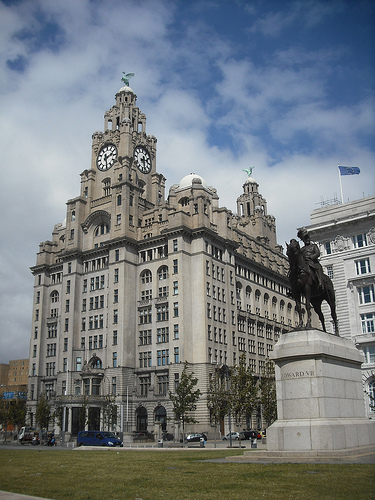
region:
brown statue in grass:
[277, 228, 370, 324]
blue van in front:
[76, 421, 129, 464]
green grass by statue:
[78, 456, 151, 489]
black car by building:
[182, 429, 220, 447]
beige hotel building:
[30, 259, 267, 371]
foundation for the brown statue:
[258, 319, 359, 454]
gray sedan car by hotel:
[212, 425, 250, 443]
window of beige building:
[68, 290, 129, 312]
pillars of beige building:
[57, 402, 99, 435]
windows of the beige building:
[196, 264, 237, 355]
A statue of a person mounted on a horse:
[260, 217, 371, 431]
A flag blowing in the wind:
[325, 148, 363, 203]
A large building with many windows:
[2, 65, 299, 452]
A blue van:
[67, 423, 134, 448]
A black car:
[170, 428, 209, 445]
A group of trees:
[165, 360, 285, 443]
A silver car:
[218, 427, 244, 442]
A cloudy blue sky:
[0, 0, 373, 147]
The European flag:
[325, 159, 365, 205]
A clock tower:
[70, 63, 175, 209]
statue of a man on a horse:
[265, 214, 350, 368]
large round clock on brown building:
[82, 109, 142, 194]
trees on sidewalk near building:
[168, 356, 266, 422]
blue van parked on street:
[56, 416, 126, 459]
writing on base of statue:
[268, 361, 324, 394]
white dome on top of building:
[161, 161, 224, 206]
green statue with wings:
[231, 155, 266, 196]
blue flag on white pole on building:
[324, 146, 369, 212]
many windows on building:
[25, 264, 274, 394]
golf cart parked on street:
[1, 414, 48, 456]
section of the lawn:
[97, 467, 114, 482]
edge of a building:
[203, 377, 204, 393]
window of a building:
[154, 384, 160, 386]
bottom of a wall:
[271, 451, 284, 455]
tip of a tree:
[245, 390, 250, 396]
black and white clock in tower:
[98, 143, 118, 171]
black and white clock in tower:
[131, 147, 153, 173]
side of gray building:
[134, 248, 185, 364]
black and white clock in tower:
[35, 269, 127, 393]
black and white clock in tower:
[192, 257, 248, 362]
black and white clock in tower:
[236, 265, 267, 364]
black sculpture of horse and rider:
[274, 229, 340, 332]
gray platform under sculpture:
[276, 343, 353, 453]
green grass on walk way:
[18, 450, 229, 496]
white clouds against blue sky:
[13, 10, 362, 67]